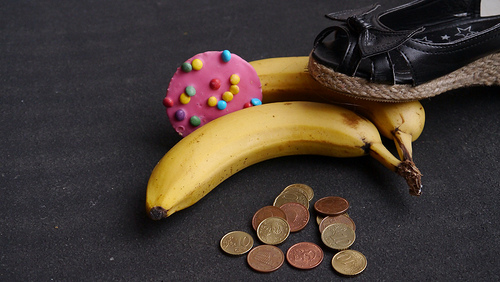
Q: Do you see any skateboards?
A: No, there are no skateboards.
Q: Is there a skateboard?
A: No, there are no skateboards.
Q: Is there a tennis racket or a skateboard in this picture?
A: No, there are no skateboards or rackets.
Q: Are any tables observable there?
A: Yes, there is a table.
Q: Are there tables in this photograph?
A: Yes, there is a table.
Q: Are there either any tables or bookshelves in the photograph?
A: Yes, there is a table.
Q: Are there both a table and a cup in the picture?
A: No, there is a table but no cups.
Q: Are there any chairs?
A: No, there are no chairs.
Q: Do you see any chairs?
A: No, there are no chairs.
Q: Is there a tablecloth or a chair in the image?
A: No, there are no chairs or tablecloths.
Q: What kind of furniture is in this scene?
A: The furniture is a table.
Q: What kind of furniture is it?
A: The piece of furniture is a table.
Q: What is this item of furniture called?
A: This is a table.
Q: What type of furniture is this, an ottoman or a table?
A: This is a table.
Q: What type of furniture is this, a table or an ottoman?
A: This is a table.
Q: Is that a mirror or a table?
A: That is a table.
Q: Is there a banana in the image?
A: Yes, there is a banana.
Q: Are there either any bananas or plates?
A: Yes, there is a banana.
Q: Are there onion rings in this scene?
A: No, there are no onion rings.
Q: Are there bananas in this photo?
A: Yes, there is a banana.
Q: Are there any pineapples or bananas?
A: Yes, there is a banana.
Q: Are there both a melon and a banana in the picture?
A: No, there is a banana but no melons.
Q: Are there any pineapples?
A: No, there are no pineapples.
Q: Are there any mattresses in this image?
A: No, there are no mattresses.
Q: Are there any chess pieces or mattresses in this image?
A: No, there are no mattresses or chess pieces.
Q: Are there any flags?
A: No, there are no flags.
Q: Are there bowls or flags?
A: No, there are no flags or bowls.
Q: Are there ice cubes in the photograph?
A: No, there are no ice cubes.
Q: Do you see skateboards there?
A: No, there are no skateboards.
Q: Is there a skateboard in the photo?
A: No, there are no skateboards.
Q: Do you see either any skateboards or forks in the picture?
A: No, there are no skateboards or forks.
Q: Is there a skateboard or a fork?
A: No, there are no skateboards or forks.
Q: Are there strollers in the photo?
A: No, there are no strollers.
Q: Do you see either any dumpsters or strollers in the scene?
A: No, there are no strollers or dumpsters.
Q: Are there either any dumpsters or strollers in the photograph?
A: No, there are no strollers or dumpsters.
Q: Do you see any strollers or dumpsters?
A: No, there are no strollers or dumpsters.